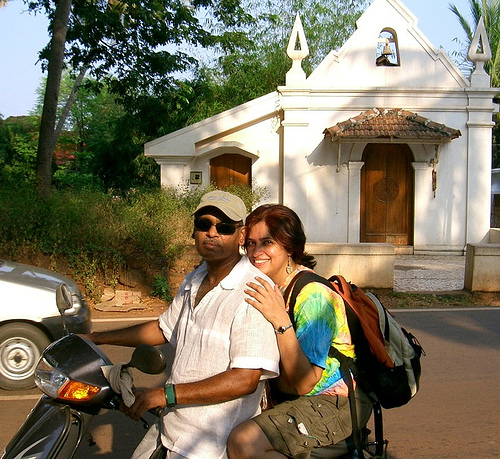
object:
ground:
[439, 302, 454, 397]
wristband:
[161, 380, 178, 410]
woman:
[242, 209, 378, 456]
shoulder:
[258, 251, 339, 297]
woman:
[224, 201, 374, 457]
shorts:
[251, 382, 374, 454]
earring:
[286, 254, 296, 274]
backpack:
[327, 268, 427, 409]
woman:
[234, 196, 377, 454]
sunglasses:
[193, 216, 246, 239]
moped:
[2, 282, 387, 456]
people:
[66, 189, 375, 456]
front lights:
[25, 357, 100, 401]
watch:
[272, 320, 297, 335]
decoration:
[371, 174, 400, 204]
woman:
[214, 206, 406, 457]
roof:
[49, 130, 95, 187]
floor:
[260, 143, 302, 227]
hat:
[191, 185, 249, 222]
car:
[0, 275, 92, 325]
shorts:
[260, 401, 341, 446]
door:
[360, 138, 416, 246]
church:
[141, 2, 496, 287]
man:
[67, 188, 282, 449]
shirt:
[156, 248, 283, 388]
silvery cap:
[7, 336, 45, 386]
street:
[25, 292, 484, 456]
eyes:
[191, 209, 242, 235]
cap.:
[189, 186, 247, 223]